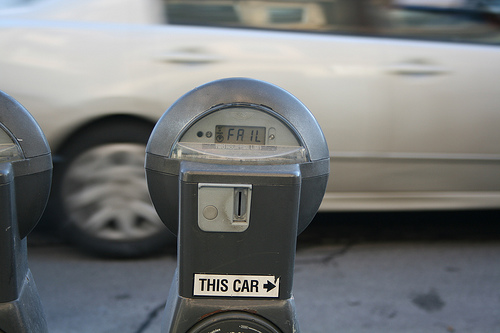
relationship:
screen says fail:
[209, 114, 266, 151] [230, 127, 268, 143]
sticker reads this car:
[197, 271, 279, 301] [198, 273, 256, 297]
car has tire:
[5, 6, 492, 243] [48, 134, 166, 247]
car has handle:
[5, 6, 492, 243] [155, 47, 229, 75]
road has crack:
[370, 249, 464, 305] [135, 305, 171, 328]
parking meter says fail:
[145, 82, 333, 322] [230, 127, 268, 143]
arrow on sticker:
[255, 274, 285, 296] [197, 271, 279, 301]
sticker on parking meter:
[197, 271, 279, 301] [145, 82, 333, 322]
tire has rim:
[48, 134, 166, 247] [68, 152, 159, 243]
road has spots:
[370, 249, 464, 305] [402, 297, 451, 321]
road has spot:
[370, 249, 464, 305] [333, 281, 369, 319]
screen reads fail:
[209, 114, 266, 151] [230, 127, 268, 143]